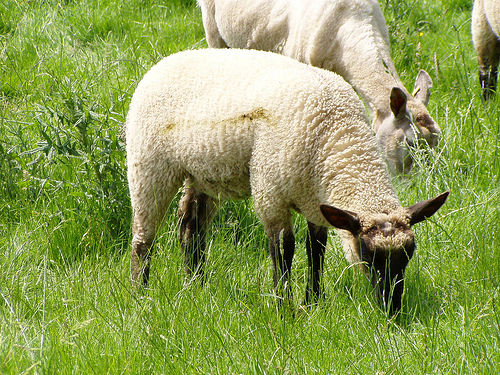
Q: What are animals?
A: Sheep.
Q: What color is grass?
A: Green.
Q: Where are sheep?
A: In field.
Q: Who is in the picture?
A: Sheep.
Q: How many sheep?
A: Three.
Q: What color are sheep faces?
A: Black.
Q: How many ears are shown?
A: Four.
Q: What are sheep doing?
A: Grazing.